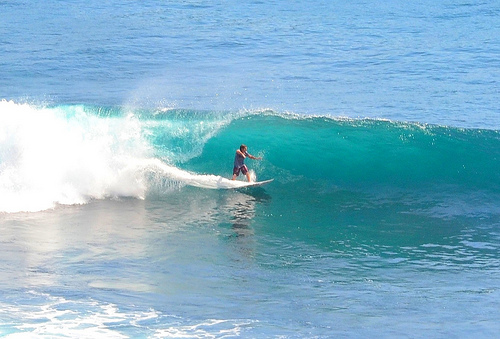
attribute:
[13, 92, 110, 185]
waves — blue, white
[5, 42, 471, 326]
ocean — white, blue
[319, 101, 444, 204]
waves — blue, white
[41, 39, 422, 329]
ocean — white, blue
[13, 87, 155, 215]
waves — blue, white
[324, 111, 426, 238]
waves — white, blue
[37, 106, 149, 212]
waves — blue, white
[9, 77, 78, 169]
waves — white, blue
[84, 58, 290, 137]
waves — blue, white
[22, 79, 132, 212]
water — splashing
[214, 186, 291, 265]
reflection — of surfer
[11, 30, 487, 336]
ocean — vast, blue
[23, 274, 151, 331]
foam — on top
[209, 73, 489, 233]
wave — still forming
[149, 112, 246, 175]
part — inner tubular part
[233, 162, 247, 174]
shorts — pair, long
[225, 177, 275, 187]
surfboard — white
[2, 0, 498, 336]
water — bluegreen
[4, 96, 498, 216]
wave — large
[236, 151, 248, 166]
shirt — blue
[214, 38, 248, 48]
ripple — small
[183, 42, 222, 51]
ripple — small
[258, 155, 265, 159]
hand — extended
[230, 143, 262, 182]
man — surfing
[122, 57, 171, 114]
mist — light, water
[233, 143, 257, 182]
surfer — surfing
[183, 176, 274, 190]
board — white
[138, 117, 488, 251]
water — blue green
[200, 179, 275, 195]
board — white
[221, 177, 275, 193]
surfboard — white